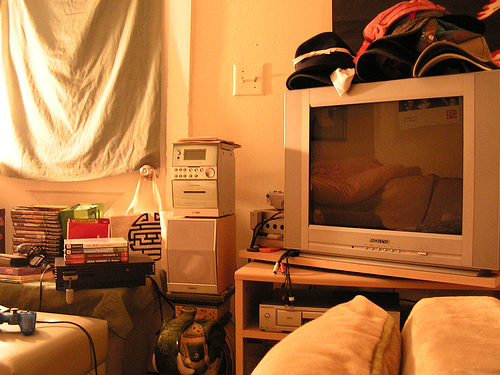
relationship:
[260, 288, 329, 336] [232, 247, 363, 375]
dvd player on stand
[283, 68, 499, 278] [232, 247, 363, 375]
tv on top of stand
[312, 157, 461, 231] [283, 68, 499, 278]
reflection inside of tv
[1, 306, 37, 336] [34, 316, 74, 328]
controller with a cord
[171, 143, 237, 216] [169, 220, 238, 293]
stero on top of speaker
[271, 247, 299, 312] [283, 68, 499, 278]
cord under tv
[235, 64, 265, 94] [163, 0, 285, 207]
light switch on wall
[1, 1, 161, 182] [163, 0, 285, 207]
sheet hanging gon wall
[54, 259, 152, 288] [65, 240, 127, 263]
game system under video games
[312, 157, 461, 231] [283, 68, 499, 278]
reflection coming from tv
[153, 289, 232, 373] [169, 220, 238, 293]
elephant holding up speaker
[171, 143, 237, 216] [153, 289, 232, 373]
stereo on elephant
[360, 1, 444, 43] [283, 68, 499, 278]
hat on top of tv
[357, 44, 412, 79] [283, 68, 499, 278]
hat on top of tv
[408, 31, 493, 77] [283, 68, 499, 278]
hat on top of tv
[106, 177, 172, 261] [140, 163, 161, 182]
bag hanging on door knob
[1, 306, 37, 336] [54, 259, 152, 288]
controller for game system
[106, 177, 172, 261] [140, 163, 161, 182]
bag hanging from door knob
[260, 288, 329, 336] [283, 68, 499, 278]
dvd player under tv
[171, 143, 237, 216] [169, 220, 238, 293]
stero with speaker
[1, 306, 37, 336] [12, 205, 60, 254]
controller for video games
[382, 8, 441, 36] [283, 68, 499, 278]
hat on top of tv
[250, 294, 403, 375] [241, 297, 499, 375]
cushion for couch